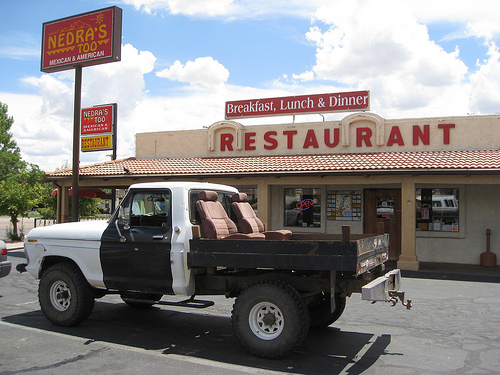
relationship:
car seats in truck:
[226, 188, 295, 241] [18, 175, 417, 357]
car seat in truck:
[190, 186, 265, 242] [18, 175, 417, 357]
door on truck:
[100, 219, 173, 292] [18, 175, 417, 357]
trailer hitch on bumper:
[390, 289, 413, 313] [361, 267, 403, 308]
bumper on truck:
[361, 267, 403, 308] [18, 175, 417, 357]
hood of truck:
[25, 213, 108, 247] [18, 175, 417, 357]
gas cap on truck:
[31, 241, 46, 255] [18, 175, 417, 357]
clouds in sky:
[301, 9, 487, 106] [1, 0, 499, 172]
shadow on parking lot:
[3, 298, 407, 374] [1, 247, 499, 374]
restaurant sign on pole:
[40, 3, 121, 76] [69, 68, 81, 225]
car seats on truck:
[226, 188, 295, 241] [18, 175, 417, 357]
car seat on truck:
[190, 186, 265, 242] [18, 175, 417, 357]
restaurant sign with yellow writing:
[40, 3, 121, 76] [45, 26, 109, 51]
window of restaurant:
[279, 184, 323, 229] [40, 113, 499, 280]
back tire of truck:
[228, 278, 311, 358] [18, 175, 417, 357]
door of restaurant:
[360, 184, 404, 263] [40, 113, 499, 280]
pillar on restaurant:
[392, 181, 421, 271] [40, 113, 499, 280]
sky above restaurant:
[1, 0, 499, 172] [40, 113, 499, 280]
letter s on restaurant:
[261, 128, 278, 153] [40, 113, 499, 280]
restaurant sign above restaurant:
[218, 90, 375, 116] [40, 113, 499, 280]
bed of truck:
[191, 227, 390, 273] [18, 175, 417, 357]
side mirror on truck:
[113, 202, 131, 242] [18, 175, 417, 357]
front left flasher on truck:
[23, 235, 43, 245] [18, 175, 417, 357]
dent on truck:
[170, 254, 177, 269] [18, 175, 417, 357]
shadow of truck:
[3, 298, 407, 374] [18, 175, 417, 357]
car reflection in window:
[415, 194, 460, 218] [415, 185, 464, 233]